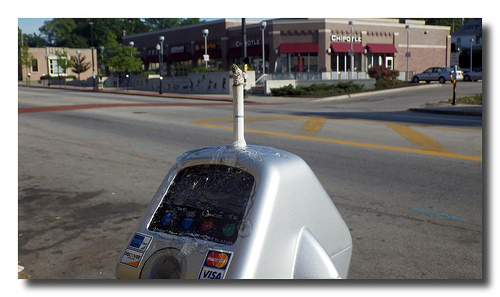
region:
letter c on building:
[330, 33, 337, 43]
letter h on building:
[335, 34, 342, 43]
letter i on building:
[341, 36, 344, 42]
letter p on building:
[342, 34, 348, 43]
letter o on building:
[346, 34, 351, 45]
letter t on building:
[350, 32, 355, 43]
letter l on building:
[354, 36, 359, 44]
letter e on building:
[358, 37, 362, 42]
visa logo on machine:
[198, 266, 225, 281]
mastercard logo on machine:
[201, 249, 233, 266]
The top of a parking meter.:
[110, 138, 355, 275]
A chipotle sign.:
[329, 30, 364, 45]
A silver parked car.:
[411, 65, 462, 84]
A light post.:
[255, 18, 268, 95]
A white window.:
[45, 55, 67, 76]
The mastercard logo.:
[205, 247, 231, 268]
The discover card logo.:
[119, 247, 146, 268]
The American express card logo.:
[125, 229, 153, 252]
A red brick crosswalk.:
[37, 98, 149, 110]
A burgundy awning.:
[366, 44, 396, 54]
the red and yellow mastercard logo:
[206, 249, 228, 266]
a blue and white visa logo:
[201, 267, 223, 279]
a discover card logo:
[121, 248, 142, 261]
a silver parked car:
[412, 63, 459, 89]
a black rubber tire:
[408, 73, 420, 82]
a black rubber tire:
[424, 78, 430, 83]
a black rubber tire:
[437, 75, 442, 81]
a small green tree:
[67, 51, 89, 76]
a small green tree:
[21, 48, 36, 80]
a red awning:
[331, 41, 367, 53]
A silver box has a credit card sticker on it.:
[113, 142, 351, 284]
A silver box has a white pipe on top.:
[111, 65, 358, 281]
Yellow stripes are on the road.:
[193, 114, 483, 161]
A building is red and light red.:
[118, 15, 449, 77]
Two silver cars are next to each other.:
[413, 63, 485, 83]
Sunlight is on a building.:
[21, 49, 100, 81]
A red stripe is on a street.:
[15, 98, 287, 112]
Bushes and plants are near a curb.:
[272, 63, 406, 103]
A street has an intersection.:
[16, 80, 481, 285]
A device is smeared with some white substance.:
[113, 143, 355, 280]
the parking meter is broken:
[98, 141, 275, 276]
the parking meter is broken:
[140, 149, 267, 261]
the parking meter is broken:
[168, 164, 255, 283]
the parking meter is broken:
[145, 162, 251, 277]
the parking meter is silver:
[129, 102, 336, 294]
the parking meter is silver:
[134, 117, 360, 289]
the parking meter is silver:
[152, 112, 332, 291]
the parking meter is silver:
[157, 117, 353, 291]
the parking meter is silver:
[116, 114, 345, 284]